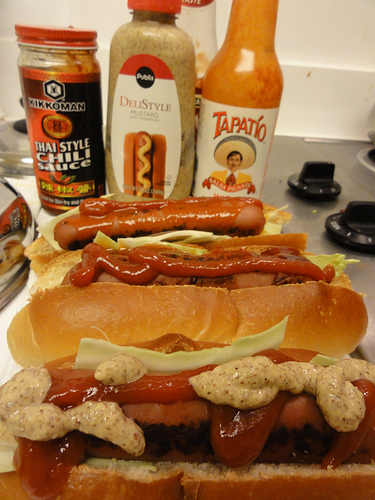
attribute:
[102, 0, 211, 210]
bottle — deli style mustard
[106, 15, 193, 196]
bottle — red, deli style mustard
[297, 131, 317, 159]
ground — under bottle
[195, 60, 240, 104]
wall — red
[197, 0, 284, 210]
bottle — hot sauce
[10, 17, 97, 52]
lid — red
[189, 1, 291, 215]
bottle — tapitio sauce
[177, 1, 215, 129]
bottle — standing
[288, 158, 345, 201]
dial — black 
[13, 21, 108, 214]
jar — chili sauce, red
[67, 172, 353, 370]
bun — red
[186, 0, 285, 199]
hot sauce — red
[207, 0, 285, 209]
bottle — hot sauce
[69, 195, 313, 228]
hotdog — delicious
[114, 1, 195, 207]
bottle — standing